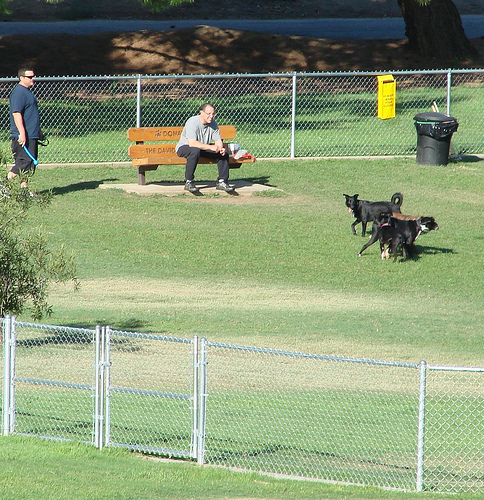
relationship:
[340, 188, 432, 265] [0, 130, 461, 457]
dogs in field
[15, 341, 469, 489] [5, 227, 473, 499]
fence in foreground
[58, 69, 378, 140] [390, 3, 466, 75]
shadow of tree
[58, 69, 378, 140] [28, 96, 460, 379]
shadow on grass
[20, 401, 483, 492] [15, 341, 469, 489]
shadow of fence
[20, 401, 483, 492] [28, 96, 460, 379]
shadow on grass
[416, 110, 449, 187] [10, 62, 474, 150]
trash can in front of fence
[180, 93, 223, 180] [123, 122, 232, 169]
man sitting on bench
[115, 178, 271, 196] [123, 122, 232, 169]
dirt under bench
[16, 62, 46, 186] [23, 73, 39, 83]
man in sunglasses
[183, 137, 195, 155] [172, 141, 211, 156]
elbow on lap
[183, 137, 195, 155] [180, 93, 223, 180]
elbow of man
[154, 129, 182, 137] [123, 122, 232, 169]
engravings on bench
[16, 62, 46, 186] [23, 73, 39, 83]
man wearing sunglasses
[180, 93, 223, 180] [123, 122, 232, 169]
man on bench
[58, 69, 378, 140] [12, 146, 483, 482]
shadow on ground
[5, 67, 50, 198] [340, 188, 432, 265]
man watching dogs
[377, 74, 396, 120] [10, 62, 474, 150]
bag dispenser on fence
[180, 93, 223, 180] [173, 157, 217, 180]
man wearing pants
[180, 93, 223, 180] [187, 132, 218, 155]
man wearing shirt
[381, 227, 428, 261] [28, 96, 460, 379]
dog on grass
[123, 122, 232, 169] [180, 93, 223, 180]
bench under man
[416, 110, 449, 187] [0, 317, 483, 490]
trash can near fence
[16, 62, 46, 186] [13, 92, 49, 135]
man wearing shirt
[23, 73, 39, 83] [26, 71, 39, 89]
sunglasses on face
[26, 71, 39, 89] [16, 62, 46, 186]
face of man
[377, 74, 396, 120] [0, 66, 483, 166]
bag dispenser on fence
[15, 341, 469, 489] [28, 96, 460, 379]
fence on grass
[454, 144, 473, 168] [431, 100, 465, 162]
broom on side of broom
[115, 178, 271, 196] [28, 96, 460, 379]
dirt in grass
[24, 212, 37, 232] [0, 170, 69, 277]
leaves on tree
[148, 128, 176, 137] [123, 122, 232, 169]
engravings on bench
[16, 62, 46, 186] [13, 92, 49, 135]
man in shirt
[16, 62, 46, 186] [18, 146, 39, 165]
man holding ball tosser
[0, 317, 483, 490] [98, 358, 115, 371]
fence with lock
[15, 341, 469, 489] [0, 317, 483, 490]
fence adjacent to fence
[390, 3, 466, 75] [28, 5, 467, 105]
tree in background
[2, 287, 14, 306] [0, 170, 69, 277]
branches of tree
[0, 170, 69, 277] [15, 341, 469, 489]
tree within fence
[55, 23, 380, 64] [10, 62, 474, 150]
dirt behind fence